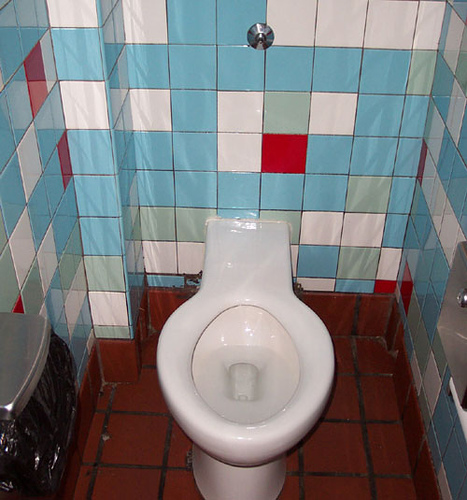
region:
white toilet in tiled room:
[13, 12, 456, 486]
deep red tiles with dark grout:
[69, 285, 427, 488]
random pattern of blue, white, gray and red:
[0, 0, 460, 341]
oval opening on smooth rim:
[156, 210, 331, 452]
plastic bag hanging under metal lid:
[0, 307, 72, 491]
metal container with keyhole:
[432, 231, 461, 407]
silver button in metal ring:
[242, 19, 272, 48]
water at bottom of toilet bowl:
[200, 339, 286, 417]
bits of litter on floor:
[74, 409, 120, 488]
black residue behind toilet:
[176, 268, 306, 293]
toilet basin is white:
[189, 228, 285, 494]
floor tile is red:
[79, 359, 186, 497]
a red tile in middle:
[228, 112, 320, 183]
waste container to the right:
[0, 307, 68, 483]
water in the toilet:
[188, 335, 282, 416]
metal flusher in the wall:
[242, 21, 280, 75]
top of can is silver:
[5, 308, 38, 423]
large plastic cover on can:
[1, 383, 75, 498]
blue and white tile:
[173, 92, 260, 174]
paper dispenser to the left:
[435, 377, 465, 438]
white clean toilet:
[154, 215, 331, 497]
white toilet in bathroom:
[153, 219, 337, 497]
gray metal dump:
[0, 311, 70, 496]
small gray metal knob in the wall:
[246, 20, 271, 50]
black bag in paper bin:
[1, 331, 83, 489]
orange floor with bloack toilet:
[61, 290, 429, 496]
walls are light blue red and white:
[4, 0, 462, 497]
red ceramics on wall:
[20, 40, 426, 312]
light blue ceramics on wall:
[5, 0, 465, 489]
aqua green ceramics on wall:
[1, 27, 465, 392]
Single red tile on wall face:
[257, 131, 307, 179]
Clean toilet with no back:
[156, 223, 338, 498]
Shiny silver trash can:
[0, 321, 75, 499]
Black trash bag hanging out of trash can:
[0, 337, 88, 497]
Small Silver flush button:
[243, 24, 281, 50]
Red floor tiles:
[64, 282, 444, 498]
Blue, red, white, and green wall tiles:
[0, 0, 466, 499]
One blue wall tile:
[167, 0, 218, 46]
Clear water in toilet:
[195, 341, 295, 425]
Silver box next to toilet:
[435, 230, 466, 410]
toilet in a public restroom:
[152, 183, 346, 491]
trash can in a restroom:
[6, 292, 86, 489]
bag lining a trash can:
[22, 335, 78, 473]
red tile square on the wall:
[258, 131, 307, 179]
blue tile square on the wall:
[170, 133, 218, 174]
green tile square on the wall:
[262, 90, 314, 141]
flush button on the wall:
[244, 21, 276, 54]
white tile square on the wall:
[132, 85, 173, 138]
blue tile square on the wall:
[358, 93, 402, 146]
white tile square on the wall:
[15, 142, 49, 180]